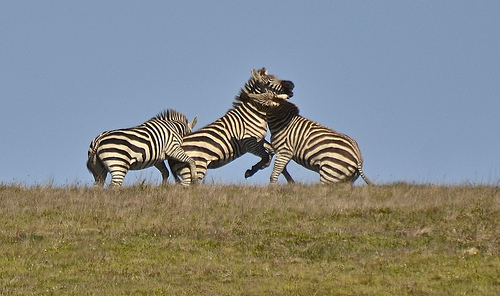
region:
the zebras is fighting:
[271, 213, 348, 280]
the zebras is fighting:
[70, 62, 355, 218]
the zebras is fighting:
[135, 95, 235, 175]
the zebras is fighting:
[161, 112, 351, 238]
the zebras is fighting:
[221, 30, 361, 270]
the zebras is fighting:
[237, 55, 293, 187]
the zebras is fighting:
[215, 56, 345, 181]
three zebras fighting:
[83, 45, 373, 195]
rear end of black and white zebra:
[84, 119, 129, 190]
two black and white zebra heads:
[231, 56, 296, 118]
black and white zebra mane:
[152, 107, 189, 126]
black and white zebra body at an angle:
[269, 115, 368, 183]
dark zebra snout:
[277, 73, 295, 93]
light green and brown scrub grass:
[110, 194, 414, 268]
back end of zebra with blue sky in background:
[321, 113, 406, 181]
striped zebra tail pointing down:
[356, 161, 373, 185]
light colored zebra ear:
[186, 109, 199, 130]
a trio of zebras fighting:
[86, 45, 366, 185]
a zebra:
[248, 86, 372, 189]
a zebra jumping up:
[173, 63, 287, 188]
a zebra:
[81, 115, 196, 193]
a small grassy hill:
[16, 185, 497, 292]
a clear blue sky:
[7, 2, 499, 179]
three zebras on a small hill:
[67, 62, 372, 207]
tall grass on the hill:
[48, 180, 498, 220]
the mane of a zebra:
[153, 105, 198, 122]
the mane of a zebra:
[280, 92, 302, 112]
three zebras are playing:
[61, 62, 401, 273]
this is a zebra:
[108, 130, 178, 163]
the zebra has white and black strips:
[126, 127, 157, 149]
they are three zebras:
[87, 83, 347, 195]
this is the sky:
[368, 17, 477, 137]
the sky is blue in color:
[388, 40, 435, 146]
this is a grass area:
[225, 220, 405, 280]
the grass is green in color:
[115, 245, 162, 265]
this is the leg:
[267, 152, 283, 192]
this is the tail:
[355, 160, 377, 185]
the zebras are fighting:
[240, 75, 296, 116]